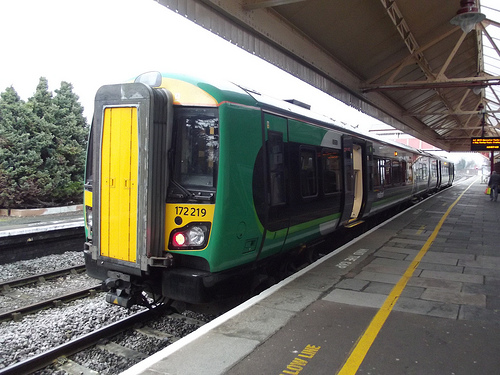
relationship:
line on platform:
[338, 178, 479, 375] [118, 181, 499, 375]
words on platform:
[278, 342, 324, 375] [118, 181, 499, 375]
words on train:
[173, 206, 209, 218] [80, 68, 455, 314]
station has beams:
[115, 0, 500, 375] [247, 2, 499, 141]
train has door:
[80, 68, 455, 314] [348, 139, 365, 219]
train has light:
[80, 68, 455, 314] [176, 228, 205, 249]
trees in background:
[1, 75, 90, 211] [1, 51, 498, 242]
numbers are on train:
[175, 205, 208, 218] [80, 68, 455, 314]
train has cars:
[80, 68, 455, 314] [412, 146, 456, 203]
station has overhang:
[115, 0, 500, 375] [151, 2, 498, 153]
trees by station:
[1, 75, 90, 211] [115, 0, 500, 375]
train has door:
[80, 68, 455, 314] [91, 83, 175, 271]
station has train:
[115, 0, 500, 375] [80, 68, 455, 314]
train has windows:
[80, 68, 455, 314] [265, 139, 403, 214]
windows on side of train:
[265, 139, 403, 214] [80, 68, 455, 314]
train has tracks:
[80, 68, 455, 314] [1, 261, 170, 375]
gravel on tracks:
[1, 252, 217, 375] [1, 261, 170, 375]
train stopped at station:
[80, 68, 455, 314] [115, 0, 500, 375]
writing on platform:
[336, 245, 370, 269] [118, 181, 499, 375]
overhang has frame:
[151, 2, 498, 153] [350, 3, 498, 141]